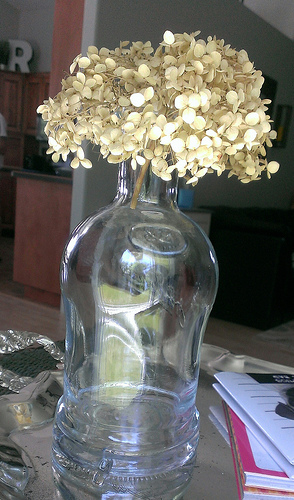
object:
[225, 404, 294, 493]
book cover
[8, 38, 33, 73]
letter r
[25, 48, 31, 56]
white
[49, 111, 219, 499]
bottle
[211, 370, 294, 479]
notebook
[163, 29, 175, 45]
petal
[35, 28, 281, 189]
flower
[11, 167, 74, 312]
counter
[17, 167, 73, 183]
top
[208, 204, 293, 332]
couch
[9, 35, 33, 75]
letter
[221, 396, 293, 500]
book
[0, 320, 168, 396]
ribbon